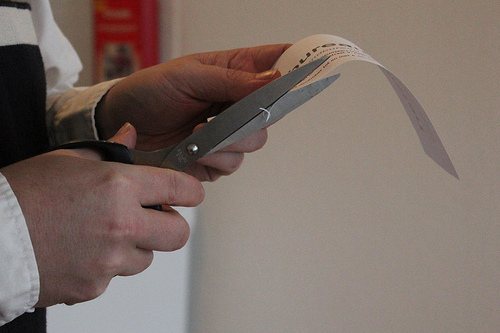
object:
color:
[401, 25, 462, 69]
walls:
[50, 3, 500, 332]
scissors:
[47, 54, 341, 212]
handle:
[46, 135, 156, 165]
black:
[105, 146, 124, 158]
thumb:
[103, 120, 138, 151]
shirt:
[0, 0, 128, 332]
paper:
[205, 33, 461, 181]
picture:
[0, 0, 499, 331]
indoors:
[48, 0, 499, 332]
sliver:
[256, 98, 277, 124]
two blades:
[173, 54, 341, 160]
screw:
[185, 142, 200, 155]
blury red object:
[88, 0, 163, 86]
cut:
[254, 54, 342, 125]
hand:
[0, 121, 207, 309]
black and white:
[11, 18, 44, 99]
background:
[0, 0, 499, 331]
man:
[0, 0, 295, 331]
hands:
[102, 42, 294, 183]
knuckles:
[95, 245, 133, 278]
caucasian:
[44, 165, 95, 202]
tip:
[310, 52, 333, 69]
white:
[5, 215, 24, 255]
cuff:
[0, 171, 41, 324]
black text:
[295, 41, 340, 64]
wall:
[46, 0, 195, 331]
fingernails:
[252, 67, 278, 82]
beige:
[396, 9, 479, 68]